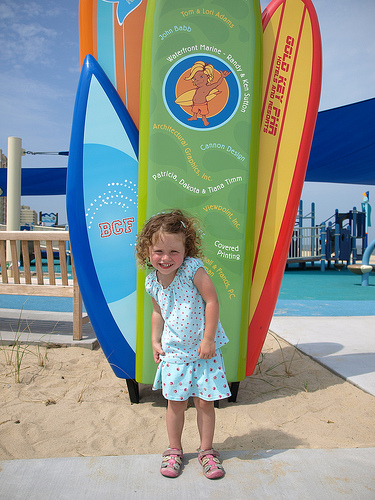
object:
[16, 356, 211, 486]
sand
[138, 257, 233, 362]
shirt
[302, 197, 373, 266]
playground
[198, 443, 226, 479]
croc sandals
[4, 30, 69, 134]
skies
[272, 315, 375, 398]
ground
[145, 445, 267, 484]
sandal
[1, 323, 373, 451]
sand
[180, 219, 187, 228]
barrette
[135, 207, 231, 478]
child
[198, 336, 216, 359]
hand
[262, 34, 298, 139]
red lettering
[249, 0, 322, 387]
sign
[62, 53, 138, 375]
surfboard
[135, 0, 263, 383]
sign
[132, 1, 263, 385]
surfboard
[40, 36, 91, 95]
wall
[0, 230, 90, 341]
bench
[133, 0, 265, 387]
green surfboard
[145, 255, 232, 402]
outfit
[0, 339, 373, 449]
sand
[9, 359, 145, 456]
sand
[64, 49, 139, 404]
blue surfboard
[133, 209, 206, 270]
clip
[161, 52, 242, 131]
picture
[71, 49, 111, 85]
tip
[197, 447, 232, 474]
sandals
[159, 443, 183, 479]
feet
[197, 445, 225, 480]
feet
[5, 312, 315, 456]
area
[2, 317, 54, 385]
grass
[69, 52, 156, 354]
surfboard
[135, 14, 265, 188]
surfboard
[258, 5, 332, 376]
surfboard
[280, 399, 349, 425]
sand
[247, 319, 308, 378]
plant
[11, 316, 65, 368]
plant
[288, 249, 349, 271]
beach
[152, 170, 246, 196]
lettering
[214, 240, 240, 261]
lettering